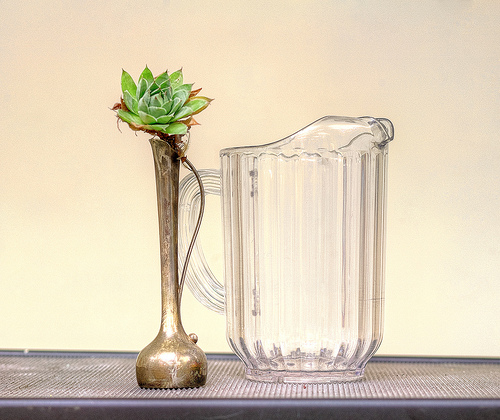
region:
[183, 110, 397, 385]
an empty jar on a table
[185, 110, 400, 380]
jar is transparent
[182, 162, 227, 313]
a handle of a jar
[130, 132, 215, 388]
a vase color gold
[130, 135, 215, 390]
vase has a long neck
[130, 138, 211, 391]
a handle on long neck of vase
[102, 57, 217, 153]
cactus on a vase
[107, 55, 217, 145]
vase is green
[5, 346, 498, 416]
a table color silver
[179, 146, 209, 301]
a thin handle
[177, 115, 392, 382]
Clear pitcher lying next to the vase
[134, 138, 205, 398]
Brown vase lying next to the pitcher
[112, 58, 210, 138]
Green flower in the vase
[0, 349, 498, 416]
Platform holding the vase and pitcher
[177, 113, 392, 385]
Pitcher used to provide water to the flower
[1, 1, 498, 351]
Light pink wall or background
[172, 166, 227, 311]
Handle of the pitcher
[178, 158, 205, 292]
Handle of the vase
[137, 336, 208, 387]
Bottom piece of the vase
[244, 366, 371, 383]
Bottom piece of the pitcher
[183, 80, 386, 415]
pitcher made of glass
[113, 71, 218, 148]
the flower is green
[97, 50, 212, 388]
a flower in flask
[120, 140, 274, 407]
the flask is gold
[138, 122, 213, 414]
the flask is gold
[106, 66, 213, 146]
green and red flower bloom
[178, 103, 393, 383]
glass pitcher with handle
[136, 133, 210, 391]
metal vase with flower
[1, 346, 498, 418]
textured table top under vase and pitcher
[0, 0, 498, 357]
the wall is beige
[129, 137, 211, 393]
the vase is metal and tarnished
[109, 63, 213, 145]
the flower is a cactus bloom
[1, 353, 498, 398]
the placemat is textured and gripped under objects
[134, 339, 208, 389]
white markings of tarnish on vase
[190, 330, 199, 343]
ball on base on handle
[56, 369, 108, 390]
White table beneath pitcher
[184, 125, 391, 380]
Clear pitcher next to vase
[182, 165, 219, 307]
Handle of water pitcher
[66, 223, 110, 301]
Tan background behind water pitcher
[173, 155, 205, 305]
Handle of flower vase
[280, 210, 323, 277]
The pitcher is clear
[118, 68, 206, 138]
Green flower in vase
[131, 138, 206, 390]
Flower vase holding a flower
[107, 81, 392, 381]
A flower vase and a water pitcher next to one another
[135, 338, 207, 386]
The bottom of the vase.